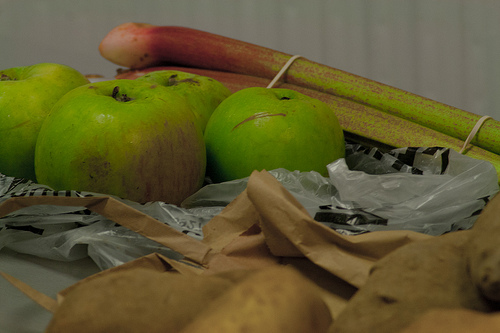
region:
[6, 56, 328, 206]
a group of apples sitting together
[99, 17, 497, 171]
another really long fruit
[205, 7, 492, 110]
the wall behind the food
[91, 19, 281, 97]
the pinker end of the fruit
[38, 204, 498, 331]
potatoes sitting on the table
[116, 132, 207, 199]
a bruised section of the apple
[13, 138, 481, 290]
bags sitting on the table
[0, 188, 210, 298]
the handle of the paper bag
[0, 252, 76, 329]
part of the table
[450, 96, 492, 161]
the rubber band holding the food together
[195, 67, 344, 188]
a large green apple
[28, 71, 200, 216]
a large green apple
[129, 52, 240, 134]
a large green apple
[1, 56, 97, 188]
a large green apple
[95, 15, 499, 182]
a bundle of rhubarb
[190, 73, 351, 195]
green apple on plastic bag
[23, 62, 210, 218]
green apple on plastic bag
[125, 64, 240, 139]
green apple on plastic bag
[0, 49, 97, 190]
green apple on plastic bag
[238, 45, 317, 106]
rubber band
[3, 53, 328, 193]
four green apples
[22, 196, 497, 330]
brown paper grocery bag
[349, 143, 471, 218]
clear plastic produce bag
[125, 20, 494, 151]
bundle of red and green vegetables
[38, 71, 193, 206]
green apple with brown spot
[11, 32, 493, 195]
fruits and vegetables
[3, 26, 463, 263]
fruits and vegetables on plastic bag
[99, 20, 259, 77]
end of a root vegetable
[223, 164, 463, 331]
paper and plastic bags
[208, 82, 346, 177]
green apple with brown mark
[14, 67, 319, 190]
green apples in front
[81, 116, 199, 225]
brown marks on side of apple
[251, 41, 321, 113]
small stem on top of apple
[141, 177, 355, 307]
brown paper bag crinkled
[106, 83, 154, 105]
another small black apple stem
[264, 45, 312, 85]
rubber band around vegetable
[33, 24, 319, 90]
red and white end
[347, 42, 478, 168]
green and red stalk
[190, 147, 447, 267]
white and black plastic bag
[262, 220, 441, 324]
group of potatoes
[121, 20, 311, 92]
rhubarb on the counter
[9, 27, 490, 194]
fruit on the counter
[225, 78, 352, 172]
apple on the counter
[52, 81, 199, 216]
apple on the counter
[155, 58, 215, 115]
apple on the counter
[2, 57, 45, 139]
apple on the counter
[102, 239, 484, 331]
potatoes on the counter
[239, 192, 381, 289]
paper bag on the counter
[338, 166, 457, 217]
plastic bag on the counter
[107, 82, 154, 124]
stem on an apple